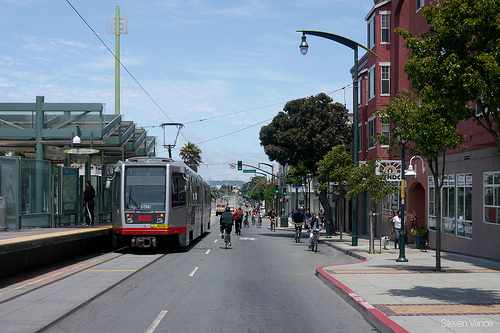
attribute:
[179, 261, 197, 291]
lines — white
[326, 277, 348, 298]
curb — red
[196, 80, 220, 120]
clouds — white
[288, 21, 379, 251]
street lamp — tall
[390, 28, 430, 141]
leaves — green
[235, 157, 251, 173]
traffic light — green, lit up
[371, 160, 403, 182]
sign — white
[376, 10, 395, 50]
window — small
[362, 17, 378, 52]
window — small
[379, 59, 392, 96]
window — small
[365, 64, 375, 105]
window — small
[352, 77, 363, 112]
window — small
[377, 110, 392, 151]
window — small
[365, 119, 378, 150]
window — small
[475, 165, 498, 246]
window — small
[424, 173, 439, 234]
window — small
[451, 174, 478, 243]
window — small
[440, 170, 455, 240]
window — small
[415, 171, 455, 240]
window — small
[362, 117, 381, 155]
window — small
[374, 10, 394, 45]
window — small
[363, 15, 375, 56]
window — small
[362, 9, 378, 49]
window — small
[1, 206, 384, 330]
road — paved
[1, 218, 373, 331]
road — paved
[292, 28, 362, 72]
streetlight — overhead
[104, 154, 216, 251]
train — red, silver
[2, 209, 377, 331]
street — paved